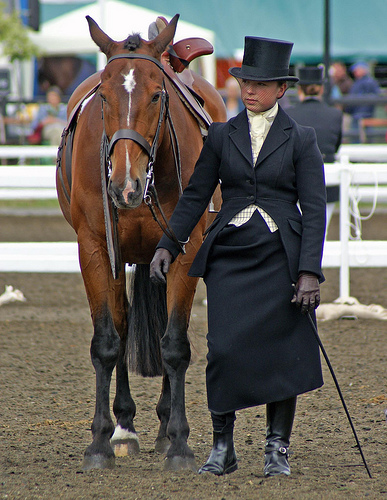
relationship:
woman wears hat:
[212, 24, 337, 423] [209, 20, 306, 109]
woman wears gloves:
[212, 24, 337, 423] [133, 250, 325, 323]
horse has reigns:
[49, 21, 210, 457] [68, 53, 186, 278]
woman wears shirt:
[212, 24, 337, 423] [243, 112, 270, 154]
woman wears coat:
[212, 24, 337, 423] [158, 108, 348, 293]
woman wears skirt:
[212, 24, 337, 423] [192, 210, 334, 405]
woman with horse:
[212, 24, 337, 423] [49, 21, 210, 457]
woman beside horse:
[212, 24, 337, 423] [49, 21, 210, 457]